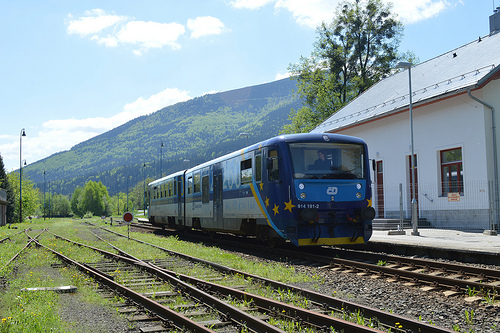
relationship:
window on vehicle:
[197, 172, 215, 209] [131, 131, 383, 251]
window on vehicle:
[286, 143, 365, 180] [136, 127, 376, 272]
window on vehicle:
[154, 183, 166, 198] [145, 132, 377, 248]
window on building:
[437, 148, 469, 198] [317, 30, 497, 238]